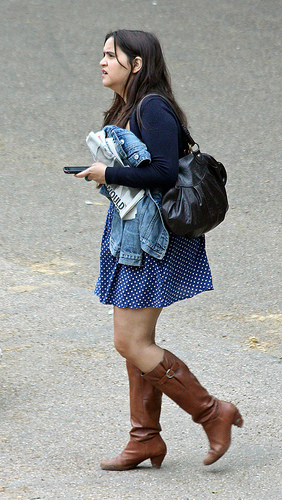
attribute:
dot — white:
[99, 253, 105, 259]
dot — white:
[147, 259, 150, 261]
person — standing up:
[62, 28, 244, 476]